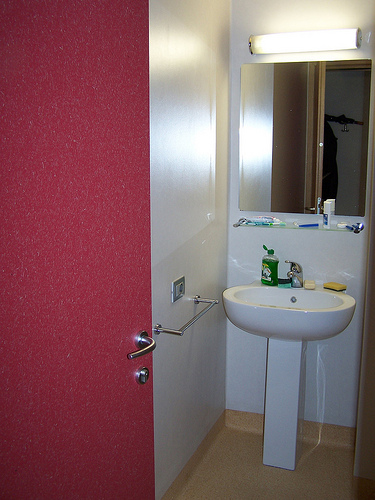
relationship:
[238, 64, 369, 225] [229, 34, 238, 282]
mirror on wall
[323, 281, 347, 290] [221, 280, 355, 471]
sponge on pedestal sink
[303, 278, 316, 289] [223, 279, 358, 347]
soap bar on sink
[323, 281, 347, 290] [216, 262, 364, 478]
sponge on sink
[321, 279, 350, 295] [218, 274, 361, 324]
sponge on sink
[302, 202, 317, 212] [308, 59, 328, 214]
door knob to door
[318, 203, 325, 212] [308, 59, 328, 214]
door knob to door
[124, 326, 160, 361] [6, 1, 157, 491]
door knob to door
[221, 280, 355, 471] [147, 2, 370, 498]
pedestal sink up against wall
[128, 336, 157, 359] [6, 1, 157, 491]
door knob on door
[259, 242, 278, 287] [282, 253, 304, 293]
soap next to faucet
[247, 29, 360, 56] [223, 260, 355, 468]
light above sink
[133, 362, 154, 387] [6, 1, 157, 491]
key on door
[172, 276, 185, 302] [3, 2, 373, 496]
lightswitch in bathroom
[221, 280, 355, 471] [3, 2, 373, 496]
pedestal sink in bathroom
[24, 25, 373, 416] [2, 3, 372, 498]
bathroom inside residence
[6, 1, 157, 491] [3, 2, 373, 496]
door in bathroom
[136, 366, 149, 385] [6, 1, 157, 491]
key on door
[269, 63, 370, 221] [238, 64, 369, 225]
closet inside reflected in mirror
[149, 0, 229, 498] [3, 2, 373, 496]
wall in bathroom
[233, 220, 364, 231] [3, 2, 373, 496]
shelf in bathroom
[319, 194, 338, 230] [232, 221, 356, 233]
item resting on shelf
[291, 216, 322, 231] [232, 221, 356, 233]
item resting on shelf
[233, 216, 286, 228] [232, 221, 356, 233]
item resting on shelf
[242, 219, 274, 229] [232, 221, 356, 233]
item resting on shelf